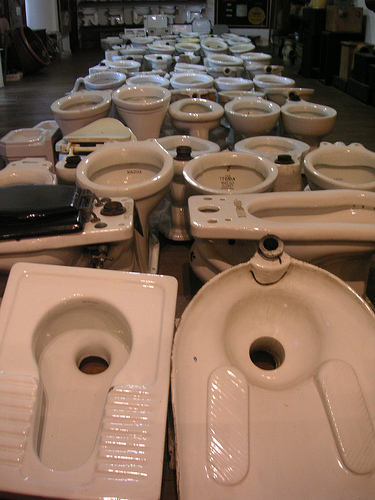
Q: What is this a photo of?
A: Toilets.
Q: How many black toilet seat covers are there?
A: One.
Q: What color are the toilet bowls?
A: White.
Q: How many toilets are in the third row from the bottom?
A: Four.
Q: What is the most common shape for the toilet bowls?
A: Circle.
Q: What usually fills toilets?
A: Water.